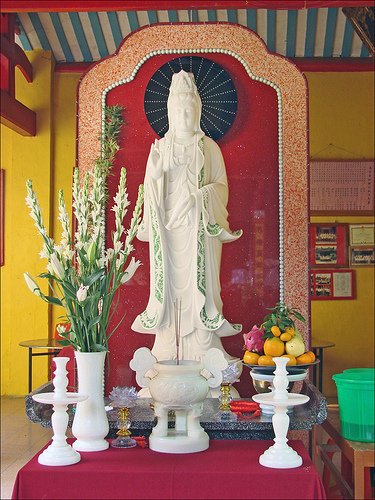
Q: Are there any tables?
A: Yes, there is a table.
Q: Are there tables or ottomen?
A: Yes, there is a table.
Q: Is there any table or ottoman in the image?
A: Yes, there is a table.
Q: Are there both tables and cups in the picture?
A: No, there is a table but no cups.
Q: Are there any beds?
A: No, there are no beds.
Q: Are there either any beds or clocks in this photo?
A: No, there are no beds or clocks.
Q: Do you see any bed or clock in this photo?
A: No, there are no beds or clocks.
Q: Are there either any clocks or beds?
A: No, there are no beds or clocks.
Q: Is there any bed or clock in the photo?
A: No, there are no beds or clocks.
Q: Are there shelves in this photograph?
A: No, there are no shelves.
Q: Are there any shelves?
A: No, there are no shelves.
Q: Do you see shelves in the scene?
A: No, there are no shelves.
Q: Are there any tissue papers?
A: No, there are no tissue papers.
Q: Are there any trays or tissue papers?
A: No, there are no tissue papers or trays.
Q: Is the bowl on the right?
A: Yes, the bowl is on the right of the image.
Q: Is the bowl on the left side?
A: No, the bowl is on the right of the image.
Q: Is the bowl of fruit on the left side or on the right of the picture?
A: The bowl is on the right of the image.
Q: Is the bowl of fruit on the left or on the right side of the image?
A: The bowl is on the right of the image.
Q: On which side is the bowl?
A: The bowl is on the right of the image.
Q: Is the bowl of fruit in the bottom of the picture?
A: Yes, the bowl is in the bottom of the image.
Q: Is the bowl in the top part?
A: No, the bowl is in the bottom of the image.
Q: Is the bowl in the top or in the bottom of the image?
A: The bowl is in the bottom of the image.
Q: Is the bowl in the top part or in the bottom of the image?
A: The bowl is in the bottom of the image.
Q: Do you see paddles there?
A: No, there are no paddles.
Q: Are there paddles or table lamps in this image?
A: No, there are no paddles or table lamps.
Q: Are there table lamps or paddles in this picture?
A: No, there are no paddles or table lamps.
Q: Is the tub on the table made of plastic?
A: Yes, the bath tub is made of plastic.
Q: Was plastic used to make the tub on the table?
A: Yes, the bath tub is made of plastic.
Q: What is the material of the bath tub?
A: The bath tub is made of plastic.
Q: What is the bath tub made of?
A: The bath tub is made of plastic.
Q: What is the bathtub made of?
A: The bath tub is made of plastic.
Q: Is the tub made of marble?
A: No, the tub is made of plastic.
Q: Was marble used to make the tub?
A: No, the tub is made of plastic.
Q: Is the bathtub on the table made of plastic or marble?
A: The bath tub is made of plastic.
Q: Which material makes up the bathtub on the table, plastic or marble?
A: The bath tub is made of plastic.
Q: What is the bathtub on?
A: The bathtub is on the table.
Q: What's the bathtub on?
A: The bathtub is on the table.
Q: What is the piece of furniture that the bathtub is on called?
A: The piece of furniture is a table.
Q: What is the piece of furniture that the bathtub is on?
A: The piece of furniture is a table.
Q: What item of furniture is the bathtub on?
A: The bathtub is on the table.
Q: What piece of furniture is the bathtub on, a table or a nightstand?
A: The bathtub is on a table.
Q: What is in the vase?
A: The flowers are in the vase.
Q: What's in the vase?
A: The flowers are in the vase.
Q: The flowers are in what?
A: The flowers are in the vase.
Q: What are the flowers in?
A: The flowers are in the vase.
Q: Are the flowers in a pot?
A: No, the flowers are in the vase.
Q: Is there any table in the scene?
A: Yes, there is a table.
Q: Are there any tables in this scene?
A: Yes, there is a table.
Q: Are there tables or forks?
A: Yes, there is a table.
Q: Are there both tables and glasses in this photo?
A: No, there is a table but no glasses.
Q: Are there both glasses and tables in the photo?
A: No, there is a table but no glasses.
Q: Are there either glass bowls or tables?
A: Yes, there is a glass table.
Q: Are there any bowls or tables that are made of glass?
A: Yes, the table is made of glass.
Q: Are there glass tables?
A: Yes, there is a table that is made of glass.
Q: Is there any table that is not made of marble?
A: Yes, there is a table that is made of glass.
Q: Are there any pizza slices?
A: No, there are no pizza slices.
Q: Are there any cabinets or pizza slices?
A: No, there are no pizza slices or cabinets.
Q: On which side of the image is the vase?
A: The vase is on the left of the image.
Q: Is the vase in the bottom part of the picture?
A: Yes, the vase is in the bottom of the image.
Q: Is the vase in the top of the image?
A: No, the vase is in the bottom of the image.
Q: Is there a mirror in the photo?
A: No, there are no mirrors.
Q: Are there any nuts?
A: No, there are no nuts.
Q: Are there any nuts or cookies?
A: No, there are no nuts or cookies.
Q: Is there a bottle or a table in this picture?
A: Yes, there is a table.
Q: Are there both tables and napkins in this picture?
A: No, there is a table but no napkins.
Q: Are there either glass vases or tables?
A: Yes, there is a glass table.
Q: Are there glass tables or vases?
A: Yes, there is a glass table.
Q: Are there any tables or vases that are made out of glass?
A: Yes, the table is made of glass.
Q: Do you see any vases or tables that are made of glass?
A: Yes, the table is made of glass.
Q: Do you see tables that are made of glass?
A: Yes, there is a table that is made of glass.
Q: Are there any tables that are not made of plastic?
A: Yes, there is a table that is made of glass.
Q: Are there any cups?
A: No, there are no cups.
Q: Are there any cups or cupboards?
A: No, there are no cups or cupboards.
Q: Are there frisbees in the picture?
A: Yes, there is a frisbee.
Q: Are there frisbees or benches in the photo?
A: Yes, there is a frisbee.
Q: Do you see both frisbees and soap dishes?
A: No, there is a frisbee but no soap dishes.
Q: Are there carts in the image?
A: No, there are no carts.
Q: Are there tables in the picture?
A: Yes, there is a table.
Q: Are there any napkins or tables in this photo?
A: Yes, there is a table.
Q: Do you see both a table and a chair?
A: No, there is a table but no chairs.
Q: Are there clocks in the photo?
A: No, there are no clocks.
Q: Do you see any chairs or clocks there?
A: No, there are no clocks or chairs.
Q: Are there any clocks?
A: No, there are no clocks.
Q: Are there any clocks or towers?
A: No, there are no clocks or towers.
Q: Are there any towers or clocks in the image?
A: No, there are no clocks or towers.